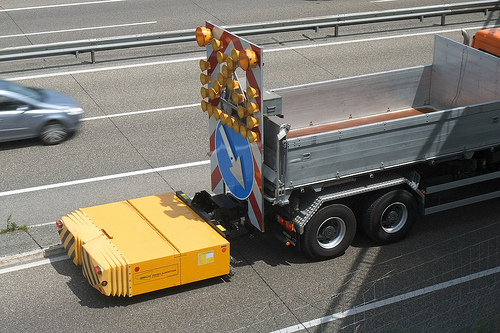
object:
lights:
[204, 20, 265, 233]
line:
[0, 159, 211, 197]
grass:
[0, 214, 27, 236]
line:
[26, 221, 55, 227]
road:
[0, 0, 500, 332]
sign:
[203, 20, 267, 235]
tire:
[36, 120, 69, 147]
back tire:
[355, 188, 421, 245]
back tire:
[296, 202, 358, 261]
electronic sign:
[56, 191, 231, 299]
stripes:
[56, 225, 102, 286]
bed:
[257, 35, 500, 208]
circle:
[214, 120, 256, 201]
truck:
[196, 19, 499, 261]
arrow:
[219, 124, 246, 190]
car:
[0, 79, 84, 146]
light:
[194, 26, 258, 144]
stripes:
[210, 127, 263, 231]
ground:
[1, 0, 498, 330]